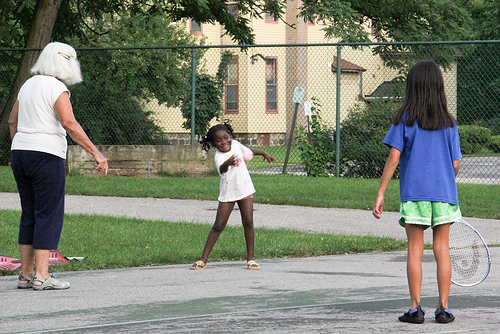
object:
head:
[200, 124, 236, 153]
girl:
[190, 123, 275, 270]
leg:
[242, 181, 259, 260]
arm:
[246, 149, 276, 164]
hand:
[220, 153, 241, 167]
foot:
[242, 257, 258, 267]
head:
[29, 42, 83, 86]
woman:
[8, 41, 108, 290]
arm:
[52, 90, 109, 175]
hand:
[94, 144, 109, 176]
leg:
[10, 148, 72, 289]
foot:
[31, 276, 73, 290]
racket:
[438, 219, 491, 286]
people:
[9, 41, 463, 325]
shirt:
[212, 139, 257, 203]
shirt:
[383, 104, 462, 204]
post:
[279, 38, 309, 185]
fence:
[0, 36, 499, 186]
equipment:
[0, 254, 89, 270]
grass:
[46, 225, 398, 267]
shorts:
[397, 200, 462, 226]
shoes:
[13, 273, 73, 288]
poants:
[4, 139, 77, 271]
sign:
[280, 87, 316, 174]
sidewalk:
[0, 185, 499, 246]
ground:
[0, 143, 499, 333]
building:
[138, 0, 457, 164]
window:
[263, 58, 278, 112]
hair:
[30, 42, 84, 84]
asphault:
[98, 257, 368, 316]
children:
[188, 60, 459, 323]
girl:
[372, 62, 464, 324]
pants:
[11, 152, 80, 258]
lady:
[7, 42, 111, 289]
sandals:
[189, 258, 209, 269]